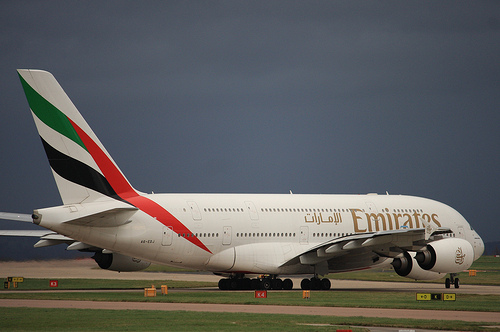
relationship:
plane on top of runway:
[0, 67, 486, 292] [3, 260, 499, 322]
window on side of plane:
[237, 233, 239, 235] [0, 67, 486, 292]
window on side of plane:
[313, 233, 316, 238] [0, 67, 486, 292]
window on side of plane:
[309, 210, 312, 213] [0, 67, 486, 292]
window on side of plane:
[213, 208, 215, 210] [0, 67, 486, 292]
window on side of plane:
[388, 209, 390, 212] [0, 67, 486, 292]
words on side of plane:
[303, 209, 441, 233] [0, 67, 486, 292]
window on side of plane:
[278, 231, 282, 236] [0, 67, 486, 292]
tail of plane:
[3, 69, 137, 263] [0, 67, 486, 292]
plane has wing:
[0, 67, 486, 292] [280, 230, 454, 276]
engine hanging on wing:
[410, 237, 472, 277] [280, 230, 454, 276]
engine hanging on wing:
[397, 249, 447, 283] [280, 230, 454, 276]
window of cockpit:
[469, 224, 473, 230] [464, 221, 478, 234]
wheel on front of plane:
[454, 277, 459, 286] [0, 67, 486, 292]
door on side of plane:
[162, 227, 172, 246] [0, 67, 486, 292]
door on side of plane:
[224, 228, 234, 245] [0, 67, 486, 292]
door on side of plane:
[190, 206, 199, 217] [0, 67, 486, 292]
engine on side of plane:
[410, 237, 472, 277] [0, 67, 486, 292]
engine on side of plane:
[397, 249, 447, 283] [0, 67, 486, 292]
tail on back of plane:
[3, 69, 137, 263] [0, 67, 486, 292]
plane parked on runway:
[0, 67, 486, 292] [3, 260, 499, 322]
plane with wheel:
[0, 67, 486, 292] [444, 276, 450, 288]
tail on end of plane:
[3, 69, 137, 263] [0, 67, 486, 292]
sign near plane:
[416, 294, 456, 300] [0, 67, 486, 292]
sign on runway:
[254, 290, 267, 297] [3, 260, 499, 322]